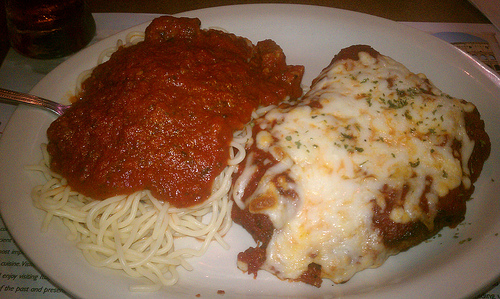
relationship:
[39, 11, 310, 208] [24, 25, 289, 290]
sauce on top noodles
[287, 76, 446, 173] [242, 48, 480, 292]
oregano on top melted cheese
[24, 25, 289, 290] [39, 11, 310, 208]
noodles with no sauce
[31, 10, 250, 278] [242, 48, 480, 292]
spaghetti and chicken parmesan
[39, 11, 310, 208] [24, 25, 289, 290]
sauce on noodles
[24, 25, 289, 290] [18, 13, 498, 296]
noodles on white plate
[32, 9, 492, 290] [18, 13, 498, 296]
food on white plate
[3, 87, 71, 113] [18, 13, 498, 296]
fork over dish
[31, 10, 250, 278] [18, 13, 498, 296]
noodles on plate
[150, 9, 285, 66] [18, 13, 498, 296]
meat on a plate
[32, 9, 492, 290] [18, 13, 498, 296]
food on plate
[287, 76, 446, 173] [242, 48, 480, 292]
vegetable seasoning on cheese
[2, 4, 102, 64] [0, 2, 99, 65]
dark beverage in cup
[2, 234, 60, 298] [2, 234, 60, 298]
newsprint has words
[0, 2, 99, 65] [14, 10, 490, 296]
glass on table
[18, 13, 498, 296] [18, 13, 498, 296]
plate on mat